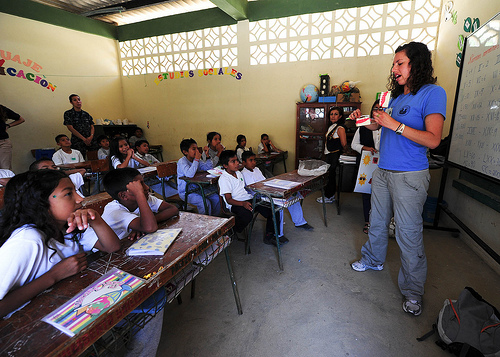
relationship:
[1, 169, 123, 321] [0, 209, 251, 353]
student sitting at desk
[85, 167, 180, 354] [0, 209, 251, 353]
student sitting at desk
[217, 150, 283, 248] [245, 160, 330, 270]
child sitting at desk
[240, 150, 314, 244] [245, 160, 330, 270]
child sitting at desk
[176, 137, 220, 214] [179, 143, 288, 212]
student sitting at desk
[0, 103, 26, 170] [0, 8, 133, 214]
teacher standing in back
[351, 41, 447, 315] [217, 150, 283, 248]
girl teaching child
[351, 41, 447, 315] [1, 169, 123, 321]
girl teaching student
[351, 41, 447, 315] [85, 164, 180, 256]
girl teaching student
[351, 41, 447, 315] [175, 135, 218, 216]
girl teaching student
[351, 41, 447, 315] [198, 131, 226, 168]
girl teaching student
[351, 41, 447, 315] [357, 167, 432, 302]
girl wearing pant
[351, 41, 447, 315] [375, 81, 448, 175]
girl wearing shirt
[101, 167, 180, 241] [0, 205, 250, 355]
student sitting at tables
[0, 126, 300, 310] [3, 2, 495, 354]
children sitting in classroom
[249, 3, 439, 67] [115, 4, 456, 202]
window on rear wall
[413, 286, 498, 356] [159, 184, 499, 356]
backpack on floor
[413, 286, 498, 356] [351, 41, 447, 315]
backpack next to girl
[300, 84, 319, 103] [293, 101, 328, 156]
globe on cabinet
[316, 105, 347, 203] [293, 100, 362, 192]
woman in front of cabinet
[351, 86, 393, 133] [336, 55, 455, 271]
cards held by teacher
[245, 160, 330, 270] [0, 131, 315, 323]
desk for children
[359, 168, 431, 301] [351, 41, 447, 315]
pants on girl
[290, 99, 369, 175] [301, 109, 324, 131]
cabinets with materials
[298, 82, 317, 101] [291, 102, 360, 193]
globe on shelf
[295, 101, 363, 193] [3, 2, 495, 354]
cabinets in classroom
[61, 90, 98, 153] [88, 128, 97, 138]
person wearing bracelet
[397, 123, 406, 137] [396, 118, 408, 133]
watch on wrist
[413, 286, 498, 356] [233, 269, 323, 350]
backpack on floor.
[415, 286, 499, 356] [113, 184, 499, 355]
backpack on ground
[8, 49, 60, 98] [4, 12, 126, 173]
writing on wall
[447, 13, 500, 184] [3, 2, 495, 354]
board for classroom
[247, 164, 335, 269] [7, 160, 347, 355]
desk in front row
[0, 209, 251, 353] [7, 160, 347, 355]
desk in front row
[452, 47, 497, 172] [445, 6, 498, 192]
writing on a board